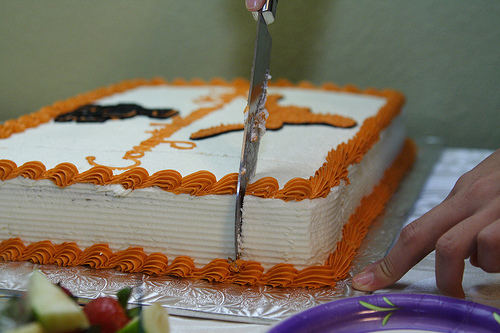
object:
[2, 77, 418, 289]
cake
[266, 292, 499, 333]
plate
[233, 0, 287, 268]
knife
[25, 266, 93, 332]
fruit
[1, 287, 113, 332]
bowl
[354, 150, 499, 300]
hand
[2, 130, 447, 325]
tray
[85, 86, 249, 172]
writing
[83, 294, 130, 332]
fruit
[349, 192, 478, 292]
middle finger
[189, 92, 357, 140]
logo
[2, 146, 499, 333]
table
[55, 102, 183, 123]
image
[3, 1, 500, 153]
wall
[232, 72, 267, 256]
icing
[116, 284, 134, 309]
leaf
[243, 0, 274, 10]
finger